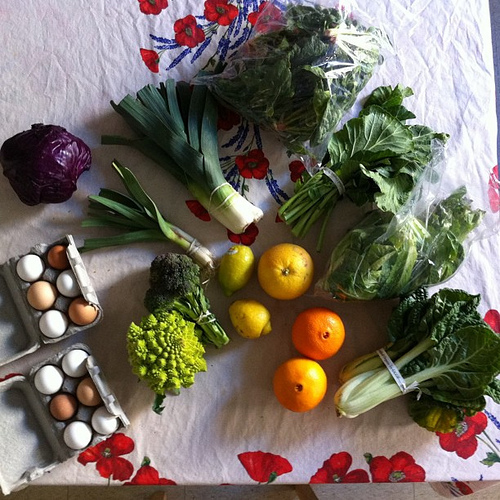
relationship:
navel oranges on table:
[265, 302, 350, 419] [2, 1, 498, 481]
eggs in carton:
[16, 246, 99, 340] [1, 346, 136, 483]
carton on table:
[1, 346, 136, 483] [2, 1, 498, 481]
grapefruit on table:
[256, 239, 316, 302] [2, 1, 498, 481]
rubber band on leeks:
[362, 350, 422, 403] [77, 73, 302, 320]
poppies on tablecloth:
[121, 2, 277, 84] [3, 1, 498, 498]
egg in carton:
[22, 360, 72, 397] [0, 339, 132, 496]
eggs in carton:
[14, 253, 96, 328] [1, 346, 136, 483]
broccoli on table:
[140, 250, 232, 353] [2, 1, 498, 481]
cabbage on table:
[2, 123, 92, 202] [2, 1, 498, 481]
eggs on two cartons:
[13, 240, 115, 455] [1, 232, 128, 494]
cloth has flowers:
[2, 1, 465, 479] [176, 16, 199, 48]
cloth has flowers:
[2, 1, 465, 479] [233, 150, 267, 179]